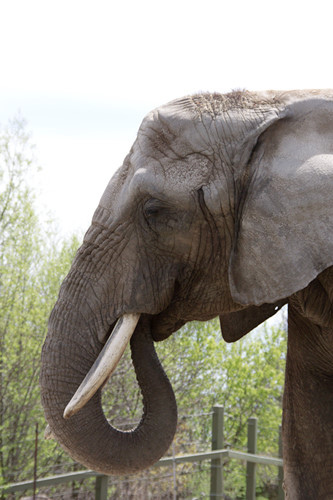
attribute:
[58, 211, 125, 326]
skin — gray, wrinkled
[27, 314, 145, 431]
tusk — grey and white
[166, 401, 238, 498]
gate — rope, steel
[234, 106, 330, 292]
ear — big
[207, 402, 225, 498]
post — green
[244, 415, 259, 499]
post — green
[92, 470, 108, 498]
post — green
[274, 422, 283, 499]
post — green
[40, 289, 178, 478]
trunk — curved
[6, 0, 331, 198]
sky — white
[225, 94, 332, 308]
ear — large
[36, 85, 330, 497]
elephant — big, grey, large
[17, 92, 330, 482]
elephant — gray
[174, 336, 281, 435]
trees — green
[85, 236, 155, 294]
skin — wrinkled, elephant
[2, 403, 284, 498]
gate — steel, rope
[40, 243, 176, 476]
trunk — curled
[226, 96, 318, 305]
ear — large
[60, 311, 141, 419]
tusk — white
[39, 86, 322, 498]
body — elephant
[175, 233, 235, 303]
skin — wrinkled